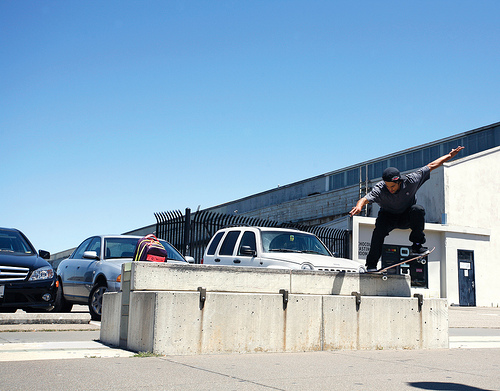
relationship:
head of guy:
[382, 167, 402, 194] [349, 145, 464, 272]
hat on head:
[381, 165, 409, 180] [382, 167, 402, 194]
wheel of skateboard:
[378, 273, 390, 283] [366, 247, 434, 280]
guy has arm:
[349, 145, 464, 272] [349, 185, 381, 217]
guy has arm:
[349, 145, 464, 272] [410, 144, 464, 184]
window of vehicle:
[261, 232, 334, 257] [199, 223, 367, 272]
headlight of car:
[29, 265, 53, 283] [0, 223, 53, 310]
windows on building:
[329, 127, 498, 190] [47, 122, 497, 308]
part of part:
[133, 234, 169, 263] [133, 234, 169, 263]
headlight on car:
[29, 265, 53, 286] [0, 228, 60, 315]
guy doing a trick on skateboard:
[349, 145, 464, 272] [366, 247, 434, 280]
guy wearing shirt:
[349, 145, 464, 272] [366, 167, 428, 213]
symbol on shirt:
[402, 189, 413, 199] [369, 165, 429, 215]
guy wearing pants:
[349, 145, 464, 272] [366, 204, 426, 269]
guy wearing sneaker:
[349, 145, 464, 272] [366, 265, 377, 274]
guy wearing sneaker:
[349, 145, 464, 272] [412, 245, 423, 257]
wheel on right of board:
[420, 257, 427, 266] [369, 250, 434, 280]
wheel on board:
[420, 257, 427, 266] [369, 250, 434, 280]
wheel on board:
[379, 273, 390, 281] [369, 250, 434, 280]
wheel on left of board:
[379, 273, 390, 281] [369, 250, 434, 280]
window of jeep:
[261, 232, 334, 257] [201, 226, 365, 275]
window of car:
[1, 230, 34, 254] [0, 228, 60, 315]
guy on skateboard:
[349, 145, 464, 272] [366, 247, 434, 280]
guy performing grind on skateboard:
[349, 145, 464, 272] [366, 247, 434, 280]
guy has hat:
[349, 145, 464, 272] [379, 159, 400, 184]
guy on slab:
[349, 145, 464, 272] [337, 272, 415, 302]